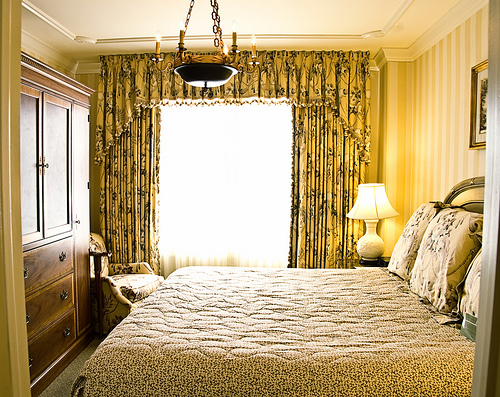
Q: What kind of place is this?
A: Hotel room.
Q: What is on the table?
A: Lamp.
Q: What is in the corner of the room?
A: Chair.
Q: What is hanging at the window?
A: Curtains.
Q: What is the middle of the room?
A: Bed.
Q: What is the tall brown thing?
A: Chest.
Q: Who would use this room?
A: Traveler.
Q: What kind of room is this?
A: Bedroom.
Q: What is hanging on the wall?
A: Picture.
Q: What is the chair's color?
A: White and black.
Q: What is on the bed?
A: Pillows.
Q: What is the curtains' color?
A: Yellow and black.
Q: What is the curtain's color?
A: White.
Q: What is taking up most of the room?
A: Bed.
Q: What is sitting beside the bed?
A: A lamp.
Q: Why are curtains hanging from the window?
A: They are keeping the sunlight out of the room.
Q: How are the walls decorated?
A: With striped wallpaper.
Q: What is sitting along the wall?
A: A brown t.v. cabinet.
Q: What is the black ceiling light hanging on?
A: Black chains.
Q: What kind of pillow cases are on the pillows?
A: Blue and white decorative pillow cases.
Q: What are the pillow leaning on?
A: A headboard.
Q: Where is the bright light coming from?
A: The sunlight.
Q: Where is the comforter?
A: On a bed.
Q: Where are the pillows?
A: By a wall.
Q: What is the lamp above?
A: A bed.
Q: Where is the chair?
A: In the corner of room.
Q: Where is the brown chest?
A: In a room.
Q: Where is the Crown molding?
A: On a ceiling.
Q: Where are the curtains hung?
A: On a window.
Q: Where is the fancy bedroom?
A: At a home or hotel.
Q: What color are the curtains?
A: Yellow.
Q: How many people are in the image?
A: No people in the image.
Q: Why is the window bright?
A: The sun is shining.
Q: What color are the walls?
A: Tan.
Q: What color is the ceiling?
A: White.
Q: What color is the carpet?
A: Green.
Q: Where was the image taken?
A: In a bedroom.